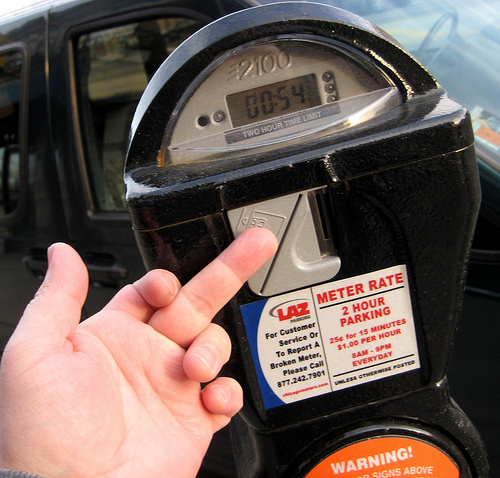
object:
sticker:
[302, 433, 458, 476]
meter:
[122, 0, 488, 474]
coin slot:
[258, 193, 304, 293]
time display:
[224, 72, 327, 128]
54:
[275, 82, 309, 111]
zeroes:
[259, 90, 275, 118]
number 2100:
[235, 48, 292, 80]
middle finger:
[146, 220, 279, 354]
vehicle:
[1, 0, 500, 468]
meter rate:
[314, 273, 406, 305]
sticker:
[240, 263, 426, 406]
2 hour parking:
[339, 297, 390, 328]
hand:
[0, 228, 280, 476]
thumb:
[3, 242, 92, 359]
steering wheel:
[417, 8, 458, 70]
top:
[124, 0, 445, 169]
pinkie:
[200, 375, 246, 419]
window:
[81, 7, 219, 217]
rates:
[328, 317, 414, 353]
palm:
[0, 327, 198, 477]